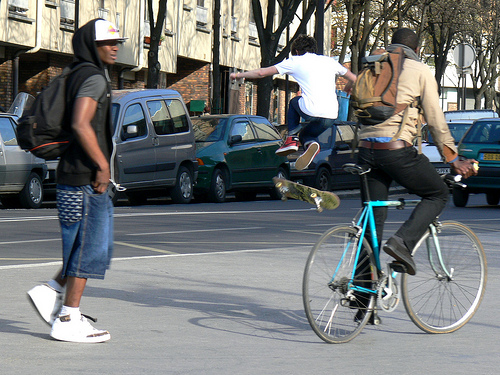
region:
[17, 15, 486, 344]
the men on the road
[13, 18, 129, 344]
the man carrying a large backpack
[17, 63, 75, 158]
the large backpack on the man's back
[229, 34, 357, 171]
the man in mid air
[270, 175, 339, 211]
the skateboard in mid air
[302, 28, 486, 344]
the man riding on the bike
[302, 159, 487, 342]
the bike the man is riding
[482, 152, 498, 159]
the license plate on the car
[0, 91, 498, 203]
the cars parked on the side of the road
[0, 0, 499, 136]
the buildings near the parked cars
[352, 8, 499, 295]
A man on a bicycle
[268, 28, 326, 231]
A man on a skateboard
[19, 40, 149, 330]
A man on the street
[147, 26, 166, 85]
A big black tree stem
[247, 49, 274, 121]
A big black tree stem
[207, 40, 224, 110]
A big black tree stem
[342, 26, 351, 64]
A big black tree stem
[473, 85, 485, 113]
A big black tree stem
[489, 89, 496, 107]
A big black tree stem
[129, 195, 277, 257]
A grey marked tarmac road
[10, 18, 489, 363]
two guys travelling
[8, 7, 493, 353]
one ignores skateboard dude, other is reasonably fascinated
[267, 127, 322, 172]
red+black hi-tops, not converse tho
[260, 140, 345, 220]
white soled hi-tops, green bottom skateboard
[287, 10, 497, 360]
good figure & work clothes on bicycle guy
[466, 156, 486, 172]
an apple or a donut in a hand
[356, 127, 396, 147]
a sky blue shirt scarcely seen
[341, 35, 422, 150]
grey scarf, brown & tan backpack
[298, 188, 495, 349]
aqua-teal bicycle, well kept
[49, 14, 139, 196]
black vest hood over white trucker cap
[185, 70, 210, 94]
a dark red brick building.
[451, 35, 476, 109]
the back of a grey street sign.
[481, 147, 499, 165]
a yellow license number.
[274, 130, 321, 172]
a man is wearing red and black sneakers.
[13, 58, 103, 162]
a man is wearing a black back pack.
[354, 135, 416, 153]
a man is wearing a brown belt.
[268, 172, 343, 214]
a light green and black skate board.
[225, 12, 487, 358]
two men one riding a bicycle and the other skateboarding.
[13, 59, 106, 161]
black backpack with red stripe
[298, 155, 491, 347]
light blue bicycle on street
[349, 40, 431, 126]
brown gray and black backpack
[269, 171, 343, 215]
yellow skateboard falling through the air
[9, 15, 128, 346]
man in white hat and black jacket walking on street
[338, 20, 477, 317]
man pedaling bicycle on street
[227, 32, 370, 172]
man in white shirt jumping off of skateboard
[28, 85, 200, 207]
gray car parked on side of street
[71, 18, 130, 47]
white baseball hat worn by young man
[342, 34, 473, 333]
young guy on a bicycle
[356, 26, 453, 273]
young guy have a book bag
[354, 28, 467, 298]
young guy wearing black pants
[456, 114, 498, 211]
one green car on the street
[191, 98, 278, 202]
one green car parked in the street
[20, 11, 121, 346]
young guy wearing white shoes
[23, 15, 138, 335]
young guy wearing a white hat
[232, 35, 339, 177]
young guy wearing white shirt